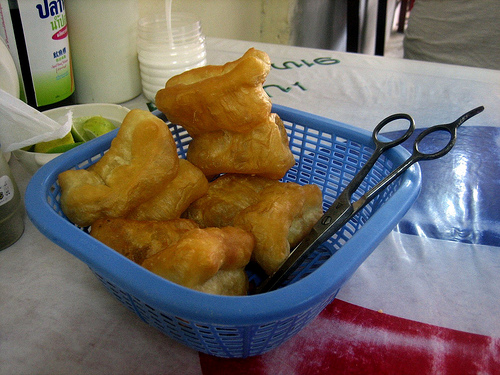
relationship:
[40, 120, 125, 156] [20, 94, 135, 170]
lime in bowl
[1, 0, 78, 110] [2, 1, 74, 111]
bottle of vanilla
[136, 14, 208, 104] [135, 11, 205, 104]
bottle of cream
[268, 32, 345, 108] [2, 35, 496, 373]
writing on table cloth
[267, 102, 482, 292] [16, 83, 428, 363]
scissors in basket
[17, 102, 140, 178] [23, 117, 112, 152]
bowl of limes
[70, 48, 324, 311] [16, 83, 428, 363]
dough in basket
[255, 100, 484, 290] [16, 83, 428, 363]
scissor in basket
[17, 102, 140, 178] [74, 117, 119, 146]
bowl of wedge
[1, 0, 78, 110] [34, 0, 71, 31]
bottle with writing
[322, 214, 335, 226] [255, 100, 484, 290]
screw in scissor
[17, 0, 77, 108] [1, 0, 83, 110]
label on bottle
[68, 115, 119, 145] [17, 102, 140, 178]
slice in bowl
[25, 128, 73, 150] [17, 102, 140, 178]
slice in bowl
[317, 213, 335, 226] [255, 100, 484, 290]
bolt on scissor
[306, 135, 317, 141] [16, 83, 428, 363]
holes on basket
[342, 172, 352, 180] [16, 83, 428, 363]
holes on basket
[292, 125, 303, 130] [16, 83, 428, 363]
holes on basket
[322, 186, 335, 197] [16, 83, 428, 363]
holes on basket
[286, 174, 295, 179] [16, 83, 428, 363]
holes on basket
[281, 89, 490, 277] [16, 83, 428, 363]
scissors in basket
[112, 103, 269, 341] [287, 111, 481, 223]
food next to scissors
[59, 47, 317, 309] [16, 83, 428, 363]
food in basket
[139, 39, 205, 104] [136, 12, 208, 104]
milk in bottle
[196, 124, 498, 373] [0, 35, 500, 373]
symbol on tablecloth